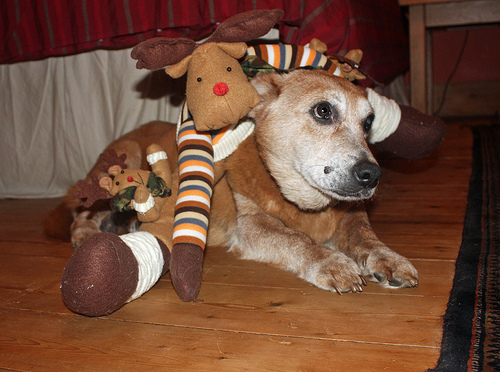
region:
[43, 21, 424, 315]
Dog with several toys piled on it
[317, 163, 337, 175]
Black growth on the edge of a dogs nose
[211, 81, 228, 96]
Red round nose of a dog toy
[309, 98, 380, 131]
Eyes of a dog giving puppy eyes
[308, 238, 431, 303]
The paws of a small dog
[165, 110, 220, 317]
Colorful arm of a dog toy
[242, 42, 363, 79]
Colorful arm of a dog toy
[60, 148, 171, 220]
Small dog toy with antlers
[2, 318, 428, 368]
Hard wood floor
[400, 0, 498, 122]
Small wooden table in the background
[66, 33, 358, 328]
Three Christmas reindeer with antlers.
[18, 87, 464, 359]
Brown wooden old time floor.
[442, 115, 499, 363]
Multi color rug on floor.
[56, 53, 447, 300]
Small brown mixed dog.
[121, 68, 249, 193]
Two red Christmas noses.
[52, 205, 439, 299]
Three brown and white paws.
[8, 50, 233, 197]
Off white bed skirt.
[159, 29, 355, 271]
Multi color stripped sweater.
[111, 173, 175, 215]
Green mistletoe for Christmas.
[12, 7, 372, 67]
Multi colored striped bed cover.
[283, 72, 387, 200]
a face of a puppy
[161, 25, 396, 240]
a puppy with a stuffed Rudolph on it's back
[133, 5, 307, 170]
Rudolph the Red Nose Reindeer on the back of a pupply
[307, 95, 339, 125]
an eye of a puppy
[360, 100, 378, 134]
an eye of a puppy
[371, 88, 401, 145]
an ear of a puppy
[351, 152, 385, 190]
the nose of a puppy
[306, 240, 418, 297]
the paws of a puppy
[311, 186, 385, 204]
the mouth of a puppy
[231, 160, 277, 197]
the fur of a puppy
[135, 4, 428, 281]
Stuffed moose on top of dog.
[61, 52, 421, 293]
Brown dog on floor.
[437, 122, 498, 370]
Navy and orange rug on floor.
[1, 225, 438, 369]
Brown hard wood flooring.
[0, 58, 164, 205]
White cloth hanging in the background.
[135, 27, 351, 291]
Striped shirt on stuffed moose.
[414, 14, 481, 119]
Black cord hanging from table.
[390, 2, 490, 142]
Wood table in the background.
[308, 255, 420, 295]
Long brown nails on dogs paws.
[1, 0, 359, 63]
Red and gray stripped material hanging in background.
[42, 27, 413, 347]
dog on the floor.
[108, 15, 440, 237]
Stuffed animal on the dog.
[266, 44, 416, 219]
Face of the dog.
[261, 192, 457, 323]
Feet of the dog.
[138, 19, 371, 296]
Reindeer stuffed animal on the dog.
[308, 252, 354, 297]
Claws on the dog.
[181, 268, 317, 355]
Wood planks on the floor.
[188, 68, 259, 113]
Red nose on the reindeer.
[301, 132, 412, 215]
Black nose on the dog.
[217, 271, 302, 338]
Crack in the floor.